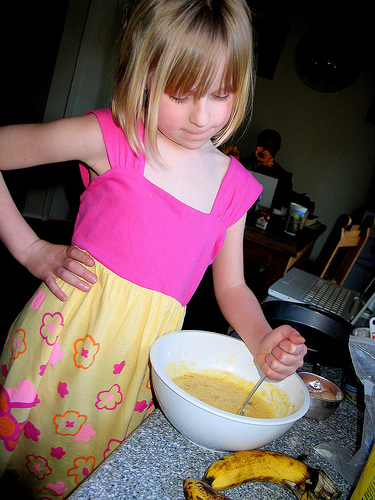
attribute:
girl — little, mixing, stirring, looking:
[1, 1, 308, 500]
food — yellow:
[168, 363, 279, 430]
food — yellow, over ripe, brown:
[175, 445, 343, 499]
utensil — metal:
[235, 366, 272, 417]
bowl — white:
[144, 322, 313, 454]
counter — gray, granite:
[58, 324, 374, 498]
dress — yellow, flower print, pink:
[2, 106, 263, 498]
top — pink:
[61, 101, 267, 308]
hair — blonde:
[99, 0, 265, 168]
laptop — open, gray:
[266, 259, 374, 329]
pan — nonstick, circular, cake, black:
[255, 293, 358, 374]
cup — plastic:
[278, 196, 310, 243]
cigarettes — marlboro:
[252, 207, 270, 235]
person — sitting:
[244, 124, 293, 194]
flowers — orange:
[223, 141, 278, 174]